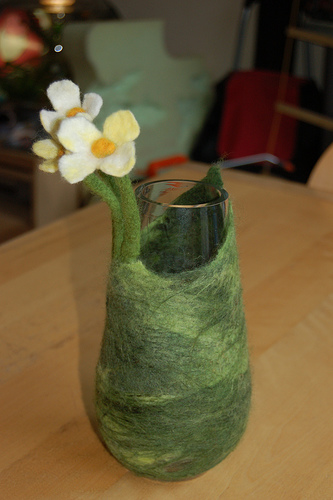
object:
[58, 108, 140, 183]
fake flower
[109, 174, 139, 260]
stem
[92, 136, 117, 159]
pistil